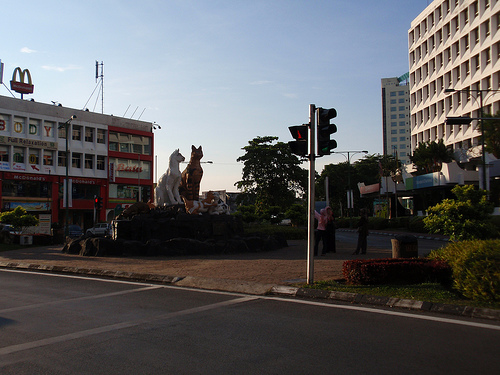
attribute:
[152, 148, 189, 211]
statues — large, cat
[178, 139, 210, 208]
statues — cat, large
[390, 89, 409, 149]
windows — many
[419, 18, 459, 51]
windows — many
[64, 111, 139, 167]
windows — many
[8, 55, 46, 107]
sign — Mcdonalds, restaurant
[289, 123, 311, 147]
light — traffic post, crosswalk post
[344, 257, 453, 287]
bushes — red, short, trimmed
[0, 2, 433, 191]
sky — blue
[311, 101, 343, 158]
light — traffic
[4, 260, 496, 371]
street — for vehicles